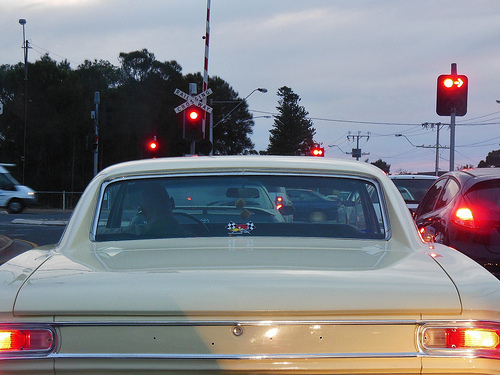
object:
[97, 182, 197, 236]
man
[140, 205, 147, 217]
ear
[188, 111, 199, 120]
lights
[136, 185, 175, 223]
head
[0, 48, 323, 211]
trees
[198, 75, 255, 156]
tree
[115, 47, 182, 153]
tree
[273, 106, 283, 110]
leaf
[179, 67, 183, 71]
leaf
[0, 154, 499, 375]
car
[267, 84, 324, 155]
leaves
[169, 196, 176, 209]
ear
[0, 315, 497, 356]
light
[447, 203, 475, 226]
light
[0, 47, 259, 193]
leaves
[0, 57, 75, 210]
tree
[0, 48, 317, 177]
leaves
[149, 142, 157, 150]
light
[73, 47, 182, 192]
tree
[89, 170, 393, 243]
window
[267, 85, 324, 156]
tree